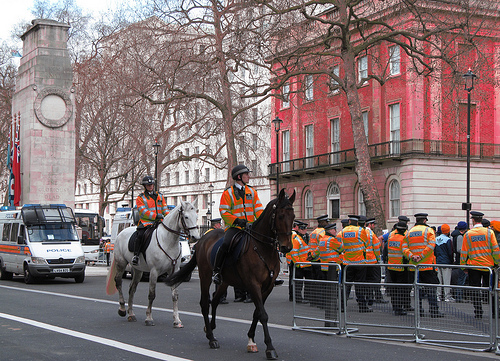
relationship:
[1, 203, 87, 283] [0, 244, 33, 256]
police van has stripe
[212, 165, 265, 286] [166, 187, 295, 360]
policeman on top of horse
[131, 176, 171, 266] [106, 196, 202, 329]
policeman on top of horse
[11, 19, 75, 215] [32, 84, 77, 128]
clocktower has place-for-clock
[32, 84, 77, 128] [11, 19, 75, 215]
place-for-clock on clocktower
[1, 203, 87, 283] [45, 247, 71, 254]
police van has police sign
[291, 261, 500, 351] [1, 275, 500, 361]
barricade on top of street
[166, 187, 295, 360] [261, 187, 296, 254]
horse has head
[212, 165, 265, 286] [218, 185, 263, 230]
policeman wearing vest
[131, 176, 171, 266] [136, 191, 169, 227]
policeman wearing vest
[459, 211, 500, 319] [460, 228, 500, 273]
cops wearing vest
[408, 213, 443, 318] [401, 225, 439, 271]
cops wearing vest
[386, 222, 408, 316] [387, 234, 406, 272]
cops wearing vest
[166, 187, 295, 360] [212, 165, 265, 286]
horse beneath policeman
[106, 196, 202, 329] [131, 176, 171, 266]
horse beneath policeman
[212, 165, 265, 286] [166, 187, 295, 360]
policeman riding on horse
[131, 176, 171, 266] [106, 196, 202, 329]
policeman riding on horse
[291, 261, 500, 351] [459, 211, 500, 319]
barricade behind cops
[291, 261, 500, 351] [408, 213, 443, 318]
barricade behind cops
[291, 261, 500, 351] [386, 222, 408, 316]
barricade behind cops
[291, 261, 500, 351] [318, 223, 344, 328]
barricade behind cops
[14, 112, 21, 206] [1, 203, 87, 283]
flag next to police van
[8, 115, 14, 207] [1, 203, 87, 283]
flag next to police van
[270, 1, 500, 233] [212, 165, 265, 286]
building behind policeman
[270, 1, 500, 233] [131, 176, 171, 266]
building behind policeman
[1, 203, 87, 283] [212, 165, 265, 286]
police van behind policeman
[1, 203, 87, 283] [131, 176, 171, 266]
police van behind policeman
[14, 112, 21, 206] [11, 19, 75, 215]
flag next to clocktower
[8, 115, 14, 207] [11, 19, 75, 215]
flag next to clocktower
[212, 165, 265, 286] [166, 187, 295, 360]
policeman has horse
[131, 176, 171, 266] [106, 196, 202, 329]
policeman has horse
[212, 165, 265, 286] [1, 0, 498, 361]
policeman in city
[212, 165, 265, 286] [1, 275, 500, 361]
policeman within street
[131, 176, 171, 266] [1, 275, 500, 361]
policeman within street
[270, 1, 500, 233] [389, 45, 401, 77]
building has window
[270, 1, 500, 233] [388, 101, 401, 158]
building has window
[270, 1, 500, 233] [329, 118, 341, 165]
building has window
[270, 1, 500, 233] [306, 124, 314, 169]
building has window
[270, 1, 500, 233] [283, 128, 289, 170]
building has window